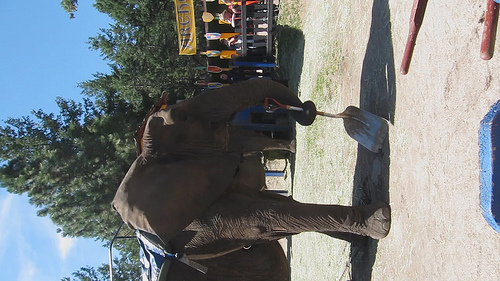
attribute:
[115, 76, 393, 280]
elephant — gray, alone, large, brown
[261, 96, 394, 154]
shovel — dirty, silver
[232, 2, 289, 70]
fence — gray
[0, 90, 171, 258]
tree — tall, green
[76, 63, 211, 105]
tree — green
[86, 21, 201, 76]
tree — green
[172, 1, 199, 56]
banner — yellow, blue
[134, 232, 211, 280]
blanket — blue, seat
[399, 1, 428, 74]
handle — wooden, red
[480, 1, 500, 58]
handle — wooden, red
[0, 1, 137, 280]
sky — blue, bright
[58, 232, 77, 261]
cloud — wispy, white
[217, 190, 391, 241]
leg — gray, wrinkly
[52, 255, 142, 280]
tree — green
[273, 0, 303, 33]
grass — green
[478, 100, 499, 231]
object — blue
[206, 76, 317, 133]
trunk — large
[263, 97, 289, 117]
handle — red